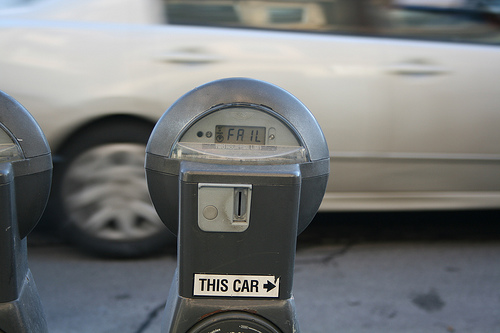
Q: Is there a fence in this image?
A: No, there are no fences.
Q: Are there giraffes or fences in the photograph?
A: No, there are no fences or giraffes.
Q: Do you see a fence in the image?
A: No, there are no fences.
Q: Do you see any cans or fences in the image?
A: No, there are no fences or cans.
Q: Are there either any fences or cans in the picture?
A: No, there are no fences or cans.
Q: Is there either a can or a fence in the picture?
A: No, there are no fences or cans.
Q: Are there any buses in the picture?
A: No, there are no buses.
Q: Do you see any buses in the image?
A: No, there are no buses.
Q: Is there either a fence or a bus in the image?
A: No, there are no buses or fences.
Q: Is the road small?
A: Yes, the road is small.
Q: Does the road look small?
A: Yes, the road is small.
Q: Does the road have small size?
A: Yes, the road is small.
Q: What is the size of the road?
A: The road is small.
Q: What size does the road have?
A: The road has small size.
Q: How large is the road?
A: The road is small.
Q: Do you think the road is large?
A: No, the road is small.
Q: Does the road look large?
A: No, the road is small.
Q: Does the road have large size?
A: No, the road is small.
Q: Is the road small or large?
A: The road is small.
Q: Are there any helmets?
A: No, there are no helmets.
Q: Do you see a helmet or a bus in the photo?
A: No, there are no helmets or buses.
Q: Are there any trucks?
A: No, there are no trucks.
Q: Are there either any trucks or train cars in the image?
A: No, there are no trucks or train cars.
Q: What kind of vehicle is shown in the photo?
A: The vehicle is a car.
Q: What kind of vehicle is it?
A: The vehicle is a car.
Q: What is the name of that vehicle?
A: This is a car.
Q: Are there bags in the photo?
A: No, there are no bags.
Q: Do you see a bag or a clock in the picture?
A: No, there are no bags or clocks.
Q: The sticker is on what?
A: The sticker is on the parking meter.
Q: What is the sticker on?
A: The sticker is on the parking meter.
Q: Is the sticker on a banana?
A: No, the sticker is on the meter.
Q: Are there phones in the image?
A: No, there are no phones.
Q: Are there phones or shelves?
A: No, there are no phones or shelves.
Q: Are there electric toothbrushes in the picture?
A: No, there are no electric toothbrushes.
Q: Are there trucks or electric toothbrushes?
A: No, there are no electric toothbrushes or trucks.